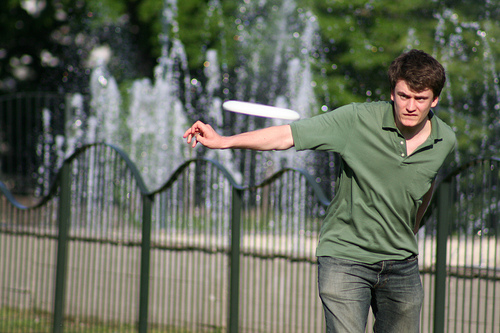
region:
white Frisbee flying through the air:
[225, 100, 298, 120]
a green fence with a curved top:
[7, 150, 498, 329]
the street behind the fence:
[2, 233, 490, 332]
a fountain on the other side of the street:
[32, 8, 487, 245]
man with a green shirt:
[180, 51, 455, 331]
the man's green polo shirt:
[290, 103, 457, 260]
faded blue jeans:
[318, 257, 423, 331]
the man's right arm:
[182, 101, 351, 148]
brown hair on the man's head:
[391, 51, 444, 98]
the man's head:
[390, 51, 445, 124]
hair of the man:
[403, 46, 444, 89]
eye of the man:
[398, 93, 412, 103]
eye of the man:
[412, 91, 434, 103]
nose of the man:
[405, 103, 415, 114]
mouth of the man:
[389, 108, 421, 119]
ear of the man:
[384, 88, 398, 103]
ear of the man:
[428, 94, 440, 108]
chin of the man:
[403, 115, 417, 135]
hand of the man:
[175, 117, 232, 151]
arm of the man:
[230, 126, 305, 151]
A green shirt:
[346, 103, 414, 237]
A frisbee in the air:
[222, 85, 299, 132]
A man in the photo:
[315, 38, 461, 260]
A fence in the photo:
[142, 168, 279, 285]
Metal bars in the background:
[114, 162, 246, 288]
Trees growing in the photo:
[129, 24, 359, 74]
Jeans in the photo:
[326, 270, 415, 330]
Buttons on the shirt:
[400, 134, 410, 166]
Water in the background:
[176, 30, 336, 86]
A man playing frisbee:
[305, 60, 455, 292]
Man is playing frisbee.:
[171, 30, 471, 317]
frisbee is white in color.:
[201, 78, 321, 141]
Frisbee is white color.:
[215, 89, 300, 130]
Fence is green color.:
[28, 145, 423, 312]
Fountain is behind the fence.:
[46, 45, 306, 225]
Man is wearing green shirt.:
[262, 85, 452, 278]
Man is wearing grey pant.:
[311, 241, 431, 331]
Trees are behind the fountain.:
[27, 37, 477, 106]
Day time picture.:
[17, 16, 473, 332]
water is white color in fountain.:
[66, 52, 319, 149]